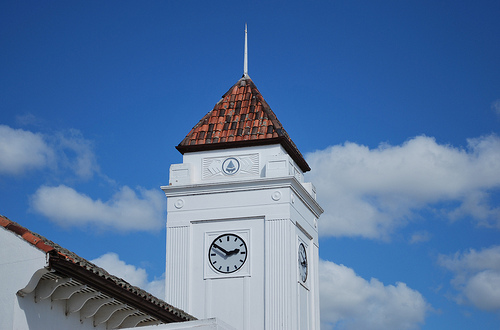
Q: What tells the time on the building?
A: Clock.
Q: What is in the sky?
A: Clouds.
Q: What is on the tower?
A: A clock.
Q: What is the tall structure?
A: A white clock tower.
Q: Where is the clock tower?
A: Attached to a building.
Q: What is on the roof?
A: Shingles.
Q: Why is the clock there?
A: To tell time.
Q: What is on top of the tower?
A: A ,metal pole.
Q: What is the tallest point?
A: The pole on the tower.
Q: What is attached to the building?
A: A clock tower.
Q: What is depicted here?
A: A tower.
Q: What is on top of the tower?
A: A pointed rod.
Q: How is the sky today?
A: Blue and clear.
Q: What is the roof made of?
A: Tiles.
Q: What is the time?
A: Quarter to 3.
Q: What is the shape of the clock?
A: Round.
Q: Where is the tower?
A: On top of the building.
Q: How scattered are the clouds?
A: Apart.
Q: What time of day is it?
A: Daytime.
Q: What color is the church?
A: White.